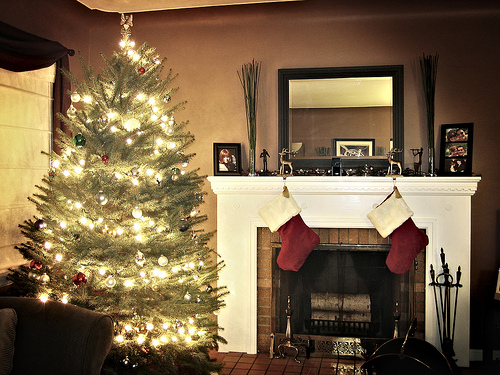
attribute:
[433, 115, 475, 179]
photos — framed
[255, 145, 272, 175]
statue — black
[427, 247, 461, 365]
fireplace tools — metal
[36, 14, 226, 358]
christmas tree — decorated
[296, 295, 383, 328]
logs — wooden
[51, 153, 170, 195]
lights — white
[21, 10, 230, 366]
christmas tree — illuminated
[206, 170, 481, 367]
fireplace — white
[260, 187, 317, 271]
stocking — red, white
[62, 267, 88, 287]
ornament — red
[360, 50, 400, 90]
ground — brown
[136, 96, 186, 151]
lights — on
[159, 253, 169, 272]
ball — red, green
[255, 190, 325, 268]
stocking — red and white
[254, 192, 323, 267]
stockings — red, white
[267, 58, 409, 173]
framed mirror — brown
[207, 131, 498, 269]
mantle — decorated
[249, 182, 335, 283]
stocking — red, white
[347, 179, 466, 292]
stocking — red, white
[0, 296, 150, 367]
couch — big